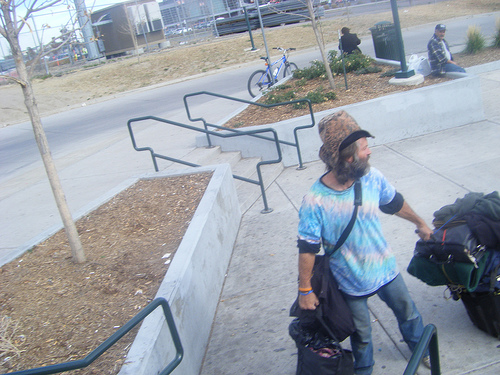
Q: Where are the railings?
A: On the steps.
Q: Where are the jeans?
A: On the man.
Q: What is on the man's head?
A: Hat.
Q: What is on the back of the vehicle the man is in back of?
A: Bags.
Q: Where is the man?
A: Parking lot.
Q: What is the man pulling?
A: Many bags.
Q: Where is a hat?
A: On man's head.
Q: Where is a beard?
A: On the man's face.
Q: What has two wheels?
A: A bicycle.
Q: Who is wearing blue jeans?
A: The man.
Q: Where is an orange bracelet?
A: Around man's wrist.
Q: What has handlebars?
A: The bicycle.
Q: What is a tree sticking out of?
A: Dirt.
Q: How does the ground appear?
A: Dirty.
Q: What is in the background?
A: Trees.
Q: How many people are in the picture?
A: 3.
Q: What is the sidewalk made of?
A: Cement.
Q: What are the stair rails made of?
A: Metal.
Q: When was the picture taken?
A: Daytime.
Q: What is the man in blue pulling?
A: Luggage.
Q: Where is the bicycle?
A: Side of the road.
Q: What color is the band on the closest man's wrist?
A: Orange.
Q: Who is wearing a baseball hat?
A: The man in the top right corner.